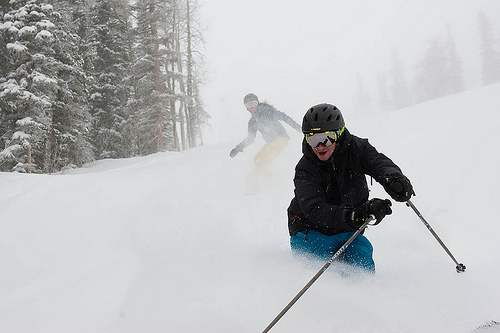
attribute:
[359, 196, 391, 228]
glove — black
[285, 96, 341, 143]
helmet — black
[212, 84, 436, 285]
person — skiing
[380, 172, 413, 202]
glove — black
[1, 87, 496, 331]
snow — large